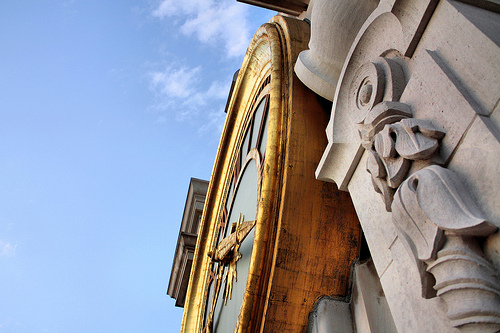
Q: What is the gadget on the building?
A: A clock.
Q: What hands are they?
A: Clock hands.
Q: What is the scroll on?
A: On the building.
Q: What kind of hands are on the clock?
A: Gold hands.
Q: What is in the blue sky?
A: Clouds.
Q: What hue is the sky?
A: Blue.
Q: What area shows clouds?
A: Sky.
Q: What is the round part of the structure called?
A: Clock.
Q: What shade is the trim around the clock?
A: Gold.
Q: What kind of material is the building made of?
A: Concrete.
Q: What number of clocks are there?
A: One.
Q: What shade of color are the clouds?
A: White.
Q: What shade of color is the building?
A: Grayish.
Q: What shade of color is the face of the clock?
A: White.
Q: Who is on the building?
A: Noone on the building.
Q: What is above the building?
A: The sky.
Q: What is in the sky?
A: A cloud.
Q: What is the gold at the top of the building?
A: A clock.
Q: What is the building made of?
A: Concrete.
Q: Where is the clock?
A: On the top of the building.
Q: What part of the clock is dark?
A: The middle.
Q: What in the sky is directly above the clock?
A: A cloud.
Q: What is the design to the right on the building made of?
A: Concrete.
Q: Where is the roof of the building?
A: Above the clock.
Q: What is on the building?
A: Clock.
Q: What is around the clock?
A: Numbers.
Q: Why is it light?
A: Daytime.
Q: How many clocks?
A: 1.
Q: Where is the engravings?
A: On the building.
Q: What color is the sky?
A: Blue.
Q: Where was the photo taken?
A: At the clock tower.